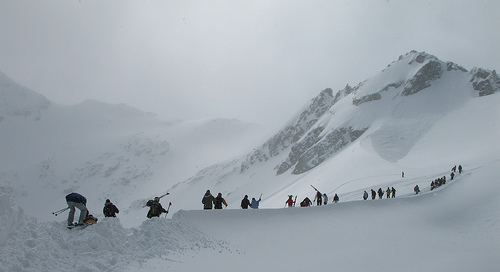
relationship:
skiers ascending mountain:
[36, 175, 431, 209] [331, 75, 485, 205]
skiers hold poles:
[36, 175, 431, 209] [142, 194, 180, 217]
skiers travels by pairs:
[36, 175, 431, 209] [191, 185, 301, 241]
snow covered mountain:
[99, 128, 210, 179] [331, 75, 485, 205]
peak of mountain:
[360, 41, 444, 79] [331, 75, 485, 205]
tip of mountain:
[379, 45, 457, 113] [331, 75, 485, 205]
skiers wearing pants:
[36, 175, 431, 209] [68, 202, 191, 240]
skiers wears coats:
[36, 175, 431, 209] [62, 182, 414, 203]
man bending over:
[57, 175, 108, 235] [26, 166, 90, 227]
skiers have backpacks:
[36, 175, 431, 209] [138, 189, 181, 234]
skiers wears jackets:
[36, 175, 431, 209] [180, 171, 339, 217]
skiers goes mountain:
[36, 175, 431, 209] [331, 75, 485, 205]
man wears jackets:
[57, 175, 108, 235] [180, 171, 339, 217]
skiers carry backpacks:
[36, 175, 431, 209] [138, 189, 181, 234]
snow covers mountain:
[99, 128, 210, 179] [331, 75, 485, 205]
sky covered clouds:
[84, 15, 291, 66] [88, 43, 270, 165]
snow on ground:
[99, 128, 210, 179] [153, 200, 309, 271]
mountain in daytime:
[331, 75, 485, 205] [84, 6, 490, 198]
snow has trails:
[99, 128, 210, 179] [126, 155, 477, 209]